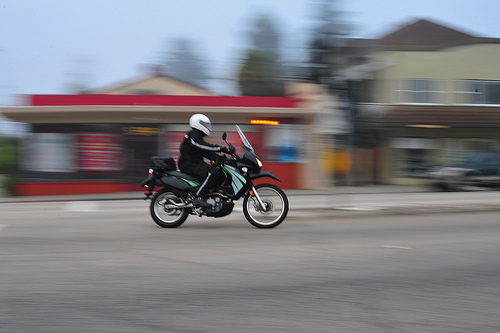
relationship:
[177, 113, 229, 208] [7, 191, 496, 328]
man in road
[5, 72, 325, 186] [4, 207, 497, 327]
building along road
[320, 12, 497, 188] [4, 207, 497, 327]
building along road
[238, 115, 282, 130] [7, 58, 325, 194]
lights on building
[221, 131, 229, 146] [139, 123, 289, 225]
sideview mirror on bike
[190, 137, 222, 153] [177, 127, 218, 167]
stripe on jacket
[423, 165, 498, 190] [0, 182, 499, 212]
parked car on side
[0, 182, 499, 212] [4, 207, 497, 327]
side on road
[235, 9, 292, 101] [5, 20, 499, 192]
tree behind building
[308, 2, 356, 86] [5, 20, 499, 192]
tree behind building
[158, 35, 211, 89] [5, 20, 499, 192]
tree behind building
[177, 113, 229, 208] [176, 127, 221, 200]
man wears clothing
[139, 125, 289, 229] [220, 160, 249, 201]
bike has trim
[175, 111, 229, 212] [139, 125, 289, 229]
man rides bike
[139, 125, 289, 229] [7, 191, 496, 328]
bike on road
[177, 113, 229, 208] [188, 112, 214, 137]
man wears helmet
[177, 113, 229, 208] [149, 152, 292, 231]
man rides motorcycle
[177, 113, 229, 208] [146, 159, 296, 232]
man rides bike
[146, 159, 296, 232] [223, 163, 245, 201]
bike has designs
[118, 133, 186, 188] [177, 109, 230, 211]
pack behind rider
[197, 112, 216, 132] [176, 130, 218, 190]
reflectors on jacket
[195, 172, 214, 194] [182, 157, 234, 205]
reflector on pants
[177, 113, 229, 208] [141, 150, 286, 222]
man on a motorcycle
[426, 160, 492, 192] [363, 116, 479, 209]
blurryvehicle in background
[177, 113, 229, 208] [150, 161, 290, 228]
man riding a motorcycle